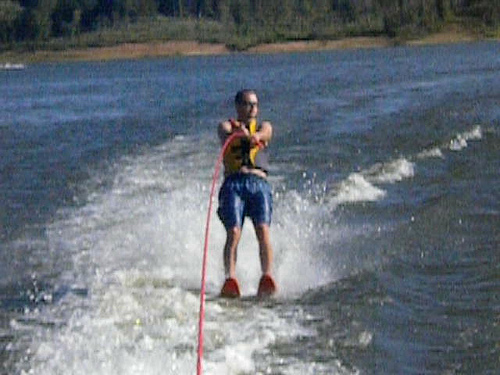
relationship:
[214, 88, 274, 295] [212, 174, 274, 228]
man wearing trunks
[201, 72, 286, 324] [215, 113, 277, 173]
man wearing lifejacket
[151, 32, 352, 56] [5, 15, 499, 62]
dirt on shoreline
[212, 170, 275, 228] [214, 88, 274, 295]
trunks on man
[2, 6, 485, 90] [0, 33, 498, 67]
vegetation on beach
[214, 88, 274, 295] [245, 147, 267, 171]
man wearing life jacket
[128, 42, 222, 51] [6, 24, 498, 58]
sand on beach